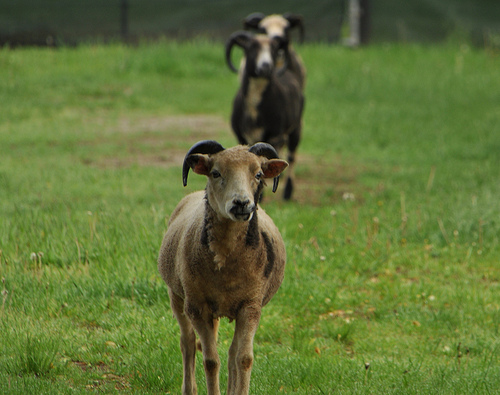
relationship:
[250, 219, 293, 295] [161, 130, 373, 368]
marking on side of ram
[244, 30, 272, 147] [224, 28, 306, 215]
marking on ram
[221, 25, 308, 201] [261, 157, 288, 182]
brown goat have ears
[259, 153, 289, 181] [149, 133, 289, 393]
ear on ram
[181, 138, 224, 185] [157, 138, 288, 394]
black horn on brown ram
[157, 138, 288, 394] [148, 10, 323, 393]
brown ram walking line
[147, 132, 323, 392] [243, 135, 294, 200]
brown ram with horn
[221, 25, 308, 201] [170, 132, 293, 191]
brown goat with horns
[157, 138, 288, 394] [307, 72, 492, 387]
brown ram walking field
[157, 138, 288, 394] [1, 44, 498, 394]
brown ram walking field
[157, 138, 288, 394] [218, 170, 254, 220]
brown ram has white muzzle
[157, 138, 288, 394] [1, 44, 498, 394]
brown ram has field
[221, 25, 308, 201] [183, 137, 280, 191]
brown goat has horns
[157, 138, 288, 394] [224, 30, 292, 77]
brown ram has horns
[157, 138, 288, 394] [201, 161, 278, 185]
brown ram has eyes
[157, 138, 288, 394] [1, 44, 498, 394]
brown ram on field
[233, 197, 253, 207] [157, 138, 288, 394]
nose on brown ram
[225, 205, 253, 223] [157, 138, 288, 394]
lips on brown ram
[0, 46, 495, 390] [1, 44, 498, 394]
flowers growing in field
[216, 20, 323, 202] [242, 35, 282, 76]
brown goat with a face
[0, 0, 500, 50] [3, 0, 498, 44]
privacy screen on fence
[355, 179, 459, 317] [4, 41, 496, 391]
grass on ground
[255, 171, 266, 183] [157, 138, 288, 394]
eye of brown ram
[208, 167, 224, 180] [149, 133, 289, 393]
eye of ram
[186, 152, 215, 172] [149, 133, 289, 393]
ear on ram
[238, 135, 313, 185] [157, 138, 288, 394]
horn on brown ram